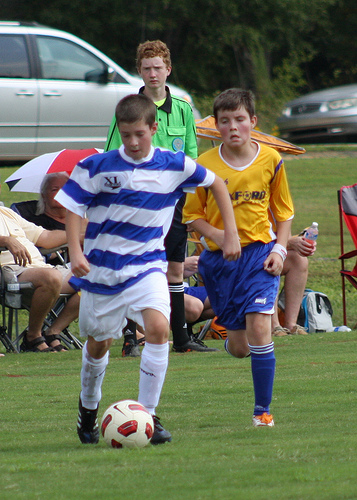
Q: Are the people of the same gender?
A: No, they are both male and female.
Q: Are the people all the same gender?
A: No, they are both male and female.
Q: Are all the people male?
A: No, they are both male and female.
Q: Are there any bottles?
A: Yes, there is a bottle.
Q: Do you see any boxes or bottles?
A: Yes, there is a bottle.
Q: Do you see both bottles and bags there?
A: Yes, there are both a bottle and a bag.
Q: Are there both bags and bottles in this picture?
A: Yes, there are both a bottle and a bag.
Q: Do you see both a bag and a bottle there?
A: Yes, there are both a bottle and a bag.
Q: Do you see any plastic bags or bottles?
A: Yes, there is a plastic bottle.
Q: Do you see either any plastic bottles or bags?
A: Yes, there is a plastic bottle.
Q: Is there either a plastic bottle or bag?
A: Yes, there is a plastic bottle.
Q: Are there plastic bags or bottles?
A: Yes, there is a plastic bottle.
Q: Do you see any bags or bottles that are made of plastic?
A: Yes, the bottle is made of plastic.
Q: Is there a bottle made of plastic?
A: Yes, there is a bottle that is made of plastic.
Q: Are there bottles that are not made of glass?
A: Yes, there is a bottle that is made of plastic.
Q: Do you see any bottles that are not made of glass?
A: Yes, there is a bottle that is made of plastic.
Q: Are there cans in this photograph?
A: No, there are no cans.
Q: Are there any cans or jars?
A: No, there are no cans or jars.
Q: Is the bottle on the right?
A: Yes, the bottle is on the right of the image.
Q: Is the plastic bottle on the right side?
A: Yes, the bottle is on the right of the image.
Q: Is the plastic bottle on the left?
A: No, the bottle is on the right of the image.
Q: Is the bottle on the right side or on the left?
A: The bottle is on the right of the image.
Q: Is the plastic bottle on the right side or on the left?
A: The bottle is on the right of the image.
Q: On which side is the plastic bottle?
A: The bottle is on the right of the image.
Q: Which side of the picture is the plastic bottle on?
A: The bottle is on the right of the image.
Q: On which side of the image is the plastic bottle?
A: The bottle is on the right of the image.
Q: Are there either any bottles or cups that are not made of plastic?
A: No, there is a bottle but it is made of plastic.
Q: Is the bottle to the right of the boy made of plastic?
A: Yes, the bottle is made of plastic.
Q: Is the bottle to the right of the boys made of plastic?
A: Yes, the bottle is made of plastic.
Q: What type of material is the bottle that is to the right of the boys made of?
A: The bottle is made of plastic.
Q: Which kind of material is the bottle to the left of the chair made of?
A: The bottle is made of plastic.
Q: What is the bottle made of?
A: The bottle is made of plastic.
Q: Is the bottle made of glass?
A: No, the bottle is made of plastic.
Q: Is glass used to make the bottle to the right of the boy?
A: No, the bottle is made of plastic.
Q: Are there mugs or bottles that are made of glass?
A: No, there is a bottle but it is made of plastic.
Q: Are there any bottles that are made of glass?
A: No, there is a bottle but it is made of plastic.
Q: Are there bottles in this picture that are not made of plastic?
A: No, there is a bottle but it is made of plastic.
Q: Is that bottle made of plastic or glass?
A: The bottle is made of plastic.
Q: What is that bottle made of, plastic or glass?
A: The bottle is made of plastic.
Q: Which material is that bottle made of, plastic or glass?
A: The bottle is made of plastic.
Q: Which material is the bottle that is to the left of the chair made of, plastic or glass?
A: The bottle is made of plastic.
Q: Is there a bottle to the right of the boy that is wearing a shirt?
A: Yes, there is a bottle to the right of the boy.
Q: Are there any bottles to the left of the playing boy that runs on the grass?
A: No, the bottle is to the right of the boy.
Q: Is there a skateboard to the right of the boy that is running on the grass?
A: No, there is a bottle to the right of the boy.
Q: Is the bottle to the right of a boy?
A: Yes, the bottle is to the right of a boy.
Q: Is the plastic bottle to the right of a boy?
A: Yes, the bottle is to the right of a boy.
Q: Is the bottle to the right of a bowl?
A: No, the bottle is to the right of a boy.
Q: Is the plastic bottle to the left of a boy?
A: No, the bottle is to the right of a boy.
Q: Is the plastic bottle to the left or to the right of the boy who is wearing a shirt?
A: The bottle is to the right of the boy.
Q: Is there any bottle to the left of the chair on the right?
A: Yes, there is a bottle to the left of the chair.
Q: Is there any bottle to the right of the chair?
A: No, the bottle is to the left of the chair.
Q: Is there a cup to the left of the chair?
A: No, there is a bottle to the left of the chair.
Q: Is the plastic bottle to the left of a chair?
A: Yes, the bottle is to the left of a chair.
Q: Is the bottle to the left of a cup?
A: No, the bottle is to the left of a chair.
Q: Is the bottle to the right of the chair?
A: No, the bottle is to the left of the chair.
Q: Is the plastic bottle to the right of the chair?
A: No, the bottle is to the left of the chair.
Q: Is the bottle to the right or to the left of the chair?
A: The bottle is to the left of the chair.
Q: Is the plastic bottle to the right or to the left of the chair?
A: The bottle is to the left of the chair.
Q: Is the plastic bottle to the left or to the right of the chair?
A: The bottle is to the left of the chair.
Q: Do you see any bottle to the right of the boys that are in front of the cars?
A: Yes, there is a bottle to the right of the boys.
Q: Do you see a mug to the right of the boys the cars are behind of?
A: No, there is a bottle to the right of the boys.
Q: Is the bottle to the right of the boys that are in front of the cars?
A: Yes, the bottle is to the right of the boys.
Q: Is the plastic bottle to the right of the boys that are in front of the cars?
A: Yes, the bottle is to the right of the boys.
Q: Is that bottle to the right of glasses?
A: No, the bottle is to the right of the boys.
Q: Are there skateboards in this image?
A: No, there are no skateboards.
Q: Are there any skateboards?
A: No, there are no skateboards.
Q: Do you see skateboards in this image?
A: No, there are no skateboards.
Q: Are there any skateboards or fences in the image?
A: No, there are no skateboards or fences.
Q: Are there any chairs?
A: Yes, there is a chair.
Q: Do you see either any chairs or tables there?
A: Yes, there is a chair.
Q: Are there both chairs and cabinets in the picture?
A: No, there is a chair but no cabinets.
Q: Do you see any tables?
A: No, there are no tables.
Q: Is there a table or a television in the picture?
A: No, there are no tables or televisions.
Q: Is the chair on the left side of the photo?
A: No, the chair is on the right of the image.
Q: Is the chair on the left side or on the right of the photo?
A: The chair is on the right of the image.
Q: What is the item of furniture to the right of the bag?
A: The piece of furniture is a chair.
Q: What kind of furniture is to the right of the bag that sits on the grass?
A: The piece of furniture is a chair.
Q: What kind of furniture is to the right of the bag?
A: The piece of furniture is a chair.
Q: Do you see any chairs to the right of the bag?
A: Yes, there is a chair to the right of the bag.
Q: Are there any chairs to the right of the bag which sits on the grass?
A: Yes, there is a chair to the right of the bag.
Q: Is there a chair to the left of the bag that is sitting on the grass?
A: No, the chair is to the right of the bag.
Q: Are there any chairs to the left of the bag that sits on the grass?
A: No, the chair is to the right of the bag.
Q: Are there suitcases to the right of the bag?
A: No, there is a chair to the right of the bag.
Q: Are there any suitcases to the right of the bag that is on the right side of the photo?
A: No, there is a chair to the right of the bag.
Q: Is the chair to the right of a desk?
A: No, the chair is to the right of the bag.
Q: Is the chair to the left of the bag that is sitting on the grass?
A: No, the chair is to the right of the bag.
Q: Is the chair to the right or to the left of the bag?
A: The chair is to the right of the bag.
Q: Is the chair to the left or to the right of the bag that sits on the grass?
A: The chair is to the right of the bag.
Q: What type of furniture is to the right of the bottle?
A: The piece of furniture is a chair.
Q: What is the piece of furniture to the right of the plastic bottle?
A: The piece of furniture is a chair.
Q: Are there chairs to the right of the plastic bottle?
A: Yes, there is a chair to the right of the bottle.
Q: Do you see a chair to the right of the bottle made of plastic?
A: Yes, there is a chair to the right of the bottle.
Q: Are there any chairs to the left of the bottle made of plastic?
A: No, the chair is to the right of the bottle.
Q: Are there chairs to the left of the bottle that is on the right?
A: No, the chair is to the right of the bottle.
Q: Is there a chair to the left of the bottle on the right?
A: No, the chair is to the right of the bottle.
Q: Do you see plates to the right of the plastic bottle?
A: No, there is a chair to the right of the bottle.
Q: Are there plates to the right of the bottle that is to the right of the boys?
A: No, there is a chair to the right of the bottle.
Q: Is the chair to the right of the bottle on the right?
A: Yes, the chair is to the right of the bottle.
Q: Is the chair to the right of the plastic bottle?
A: Yes, the chair is to the right of the bottle.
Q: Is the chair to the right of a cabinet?
A: No, the chair is to the right of the bottle.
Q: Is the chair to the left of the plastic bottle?
A: No, the chair is to the right of the bottle.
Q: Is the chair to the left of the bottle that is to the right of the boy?
A: No, the chair is to the right of the bottle.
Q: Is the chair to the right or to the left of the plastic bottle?
A: The chair is to the right of the bottle.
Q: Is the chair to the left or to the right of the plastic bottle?
A: The chair is to the right of the bottle.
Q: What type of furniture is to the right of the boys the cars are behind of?
A: The piece of furniture is a chair.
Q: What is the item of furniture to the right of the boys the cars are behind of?
A: The piece of furniture is a chair.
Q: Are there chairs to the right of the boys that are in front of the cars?
A: Yes, there is a chair to the right of the boys.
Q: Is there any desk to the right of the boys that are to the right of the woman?
A: No, there is a chair to the right of the boys.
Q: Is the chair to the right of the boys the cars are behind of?
A: Yes, the chair is to the right of the boys.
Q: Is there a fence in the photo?
A: No, there are no fences.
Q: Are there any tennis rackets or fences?
A: No, there are no fences or tennis rackets.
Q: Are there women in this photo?
A: Yes, there is a woman.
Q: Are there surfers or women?
A: Yes, there is a woman.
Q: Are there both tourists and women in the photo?
A: No, there is a woman but no tourists.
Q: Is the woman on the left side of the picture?
A: Yes, the woman is on the left of the image.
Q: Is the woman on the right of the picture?
A: No, the woman is on the left of the image.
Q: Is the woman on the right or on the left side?
A: The woman is on the left of the image.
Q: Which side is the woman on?
A: The woman is on the left of the image.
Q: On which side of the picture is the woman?
A: The woman is on the left of the image.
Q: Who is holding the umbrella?
A: The woman is holding the umbrella.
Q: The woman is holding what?
A: The woman is holding the umbrella.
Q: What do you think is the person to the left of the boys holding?
A: The woman is holding the umbrella.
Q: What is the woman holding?
A: The woman is holding the umbrella.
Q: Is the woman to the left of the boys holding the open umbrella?
A: Yes, the woman is holding the umbrella.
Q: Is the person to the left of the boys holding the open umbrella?
A: Yes, the woman is holding the umbrella.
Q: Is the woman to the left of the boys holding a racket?
A: No, the woman is holding the umbrella.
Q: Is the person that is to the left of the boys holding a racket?
A: No, the woman is holding the umbrella.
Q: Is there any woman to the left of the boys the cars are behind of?
A: Yes, there is a woman to the left of the boys.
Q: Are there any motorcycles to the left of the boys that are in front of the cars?
A: No, there is a woman to the left of the boys.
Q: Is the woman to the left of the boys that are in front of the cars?
A: Yes, the woman is to the left of the boys.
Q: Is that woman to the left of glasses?
A: No, the woman is to the left of the boys.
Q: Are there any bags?
A: Yes, there is a bag.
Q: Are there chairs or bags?
A: Yes, there is a bag.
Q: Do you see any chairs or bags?
A: Yes, there is a bag.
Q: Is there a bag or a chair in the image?
A: Yes, there is a bag.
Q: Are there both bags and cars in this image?
A: Yes, there are both a bag and a car.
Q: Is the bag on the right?
A: Yes, the bag is on the right of the image.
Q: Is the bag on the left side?
A: No, the bag is on the right of the image.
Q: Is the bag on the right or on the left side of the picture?
A: The bag is on the right of the image.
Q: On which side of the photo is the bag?
A: The bag is on the right of the image.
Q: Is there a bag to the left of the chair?
A: Yes, there is a bag to the left of the chair.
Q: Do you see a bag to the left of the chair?
A: Yes, there is a bag to the left of the chair.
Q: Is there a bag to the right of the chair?
A: No, the bag is to the left of the chair.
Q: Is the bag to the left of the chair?
A: Yes, the bag is to the left of the chair.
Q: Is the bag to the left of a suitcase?
A: No, the bag is to the left of the chair.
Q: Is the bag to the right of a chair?
A: No, the bag is to the left of a chair.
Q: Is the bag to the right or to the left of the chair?
A: The bag is to the left of the chair.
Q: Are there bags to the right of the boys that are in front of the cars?
A: Yes, there is a bag to the right of the boys.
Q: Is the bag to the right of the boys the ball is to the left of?
A: Yes, the bag is to the right of the boys.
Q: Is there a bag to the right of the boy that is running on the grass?
A: Yes, there is a bag to the right of the boy.